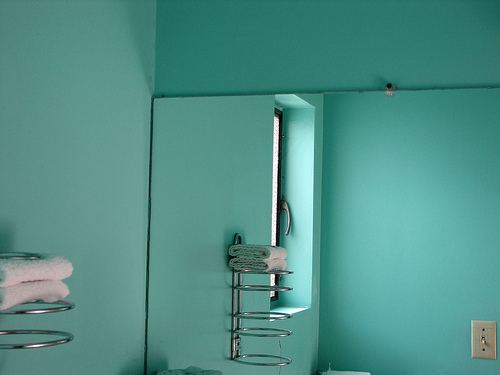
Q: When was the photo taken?
A: Daytime.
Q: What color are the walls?
A: Green.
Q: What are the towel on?
A: Towel rack.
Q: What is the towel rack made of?
A: Metal.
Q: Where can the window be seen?
A: Mirror.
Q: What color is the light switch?
A: White.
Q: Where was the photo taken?
A: In a bathroom.